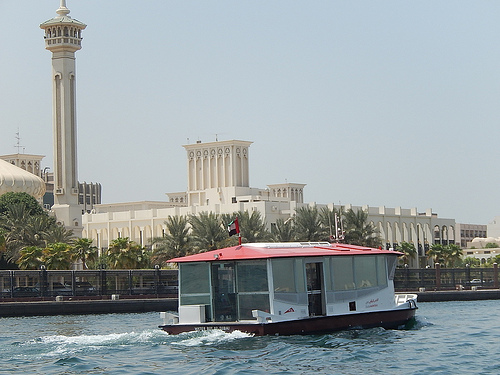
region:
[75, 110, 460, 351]
an interesting boat out on the water.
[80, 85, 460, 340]
a unique boat out on the water.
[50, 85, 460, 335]
an interesting boat on water in daytime.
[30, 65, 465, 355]
a unique boat out on water in daylight.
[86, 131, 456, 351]
a special boat traveling water.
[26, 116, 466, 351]
a unique boat traveling water.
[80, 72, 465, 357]
a special boat traveling water near the city.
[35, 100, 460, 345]
interesting boat traveling water near the city.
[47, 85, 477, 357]
nice boat traveling water near the city.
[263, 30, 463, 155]
patch of clear sky.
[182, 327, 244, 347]
White waves in the water.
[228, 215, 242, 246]
Flag on top of a boat in the water.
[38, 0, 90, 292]
Large thin tower going up into the sky.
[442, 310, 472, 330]
Ripples in the blue water.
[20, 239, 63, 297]
Palm tree on land beside the water.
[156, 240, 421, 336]
Boat with a red roof on the water.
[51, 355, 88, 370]
Waves in the water.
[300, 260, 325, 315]
Side door on a small boat in the water.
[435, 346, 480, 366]
Small waves in the blue water.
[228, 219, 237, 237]
Blue and white colors on a flag.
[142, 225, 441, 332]
Boat with a red roof.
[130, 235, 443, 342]
A single boat in the water.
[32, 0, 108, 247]
Large tower in the background.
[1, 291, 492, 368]
The water is blue.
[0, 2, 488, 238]
The sky is hazy and blue.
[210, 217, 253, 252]
Flag on top of the boat.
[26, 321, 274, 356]
Wake being left behind the boat.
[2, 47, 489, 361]
Nobody shown in the photo.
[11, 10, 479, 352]
Photo taken in the afternoon.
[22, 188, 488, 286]
Palm trees lining the street.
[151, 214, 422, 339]
a houseboat floating in the water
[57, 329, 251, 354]
waves in the water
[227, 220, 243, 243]
a flag on a houseboat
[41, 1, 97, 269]
a tall building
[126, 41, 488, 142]
a partially clear sky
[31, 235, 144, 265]
palm trees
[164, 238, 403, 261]
the roof of a houseboat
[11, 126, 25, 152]
an antenna on a building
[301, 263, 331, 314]
the door of a houseboat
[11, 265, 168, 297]
cars parked in a parking lot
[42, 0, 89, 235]
Tall white tower behind trees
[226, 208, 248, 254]
A red white and black flag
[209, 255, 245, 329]
An entrance to the boat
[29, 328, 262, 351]
White looking splashed waves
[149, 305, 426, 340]
A brown bottom ship part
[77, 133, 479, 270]
A tall white structure with many arches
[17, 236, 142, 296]
Palm trees behind the boat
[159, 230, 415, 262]
A red ship's rooftop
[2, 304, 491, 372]
A body of moving water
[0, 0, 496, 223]
Clear blue skies